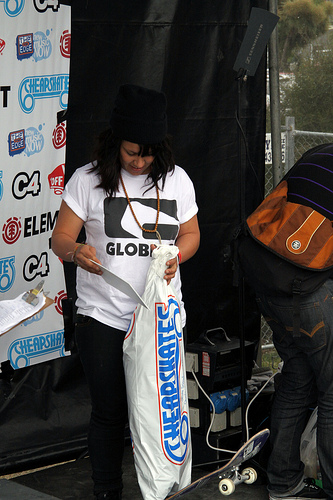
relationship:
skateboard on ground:
[163, 428, 271, 498] [114, 461, 253, 497]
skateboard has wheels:
[163, 428, 271, 498] [240, 466, 257, 484]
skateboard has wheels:
[163, 428, 271, 498] [217, 477, 236, 494]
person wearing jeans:
[255, 144, 331, 233] [255, 297, 331, 411]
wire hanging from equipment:
[189, 357, 283, 453] [64, 0, 279, 467]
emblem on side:
[6, 123, 32, 152] [2, 23, 63, 498]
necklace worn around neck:
[117, 170, 161, 233] [119, 165, 152, 175]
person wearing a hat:
[59, 104, 196, 362] [110, 93, 172, 143]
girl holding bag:
[49, 87, 200, 500] [112, 237, 190, 498]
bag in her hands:
[112, 237, 190, 498] [74, 233, 185, 281]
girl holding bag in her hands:
[49, 87, 200, 500] [74, 233, 185, 281]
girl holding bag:
[49, 87, 200, 500] [122, 243, 192, 500]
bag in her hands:
[122, 243, 192, 500] [75, 240, 193, 282]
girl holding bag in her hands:
[49, 87, 200, 500] [75, 240, 193, 282]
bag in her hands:
[122, 243, 192, 500] [61, 229, 182, 282]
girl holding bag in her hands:
[49, 87, 200, 500] [61, 229, 182, 282]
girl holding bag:
[51, 86, 290, 310] [122, 243, 192, 500]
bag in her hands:
[122, 243, 192, 500] [74, 243, 183, 281]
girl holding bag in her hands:
[51, 86, 290, 310] [74, 243, 183, 281]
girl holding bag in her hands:
[49, 87, 200, 500] [72, 241, 180, 288]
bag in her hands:
[122, 243, 192, 500] [72, 241, 180, 288]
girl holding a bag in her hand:
[49, 87, 200, 500] [164, 252, 179, 283]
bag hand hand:
[122, 243, 192, 500] [164, 252, 179, 283]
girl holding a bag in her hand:
[49, 87, 200, 500] [73, 243, 102, 275]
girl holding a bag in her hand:
[49, 87, 200, 500] [148, 244, 176, 283]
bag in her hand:
[122, 243, 192, 500] [73, 243, 102, 275]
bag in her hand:
[122, 243, 192, 500] [148, 244, 176, 283]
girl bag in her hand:
[49, 87, 200, 500] [163, 256, 178, 283]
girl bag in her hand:
[49, 87, 200, 500] [73, 243, 102, 275]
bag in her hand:
[122, 243, 192, 500] [163, 256, 178, 283]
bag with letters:
[122, 243, 192, 500] [151, 324, 179, 364]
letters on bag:
[151, 324, 179, 364] [122, 243, 192, 500]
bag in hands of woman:
[122, 243, 192, 500] [49, 81, 203, 499]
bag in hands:
[122, 243, 192, 500] [74, 239, 179, 283]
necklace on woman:
[117, 171, 160, 233] [54, 116, 202, 497]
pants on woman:
[68, 311, 127, 499] [56, 64, 245, 339]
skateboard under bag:
[163, 428, 271, 498] [122, 243, 192, 500]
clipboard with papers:
[1, 285, 55, 337] [0, 290, 39, 327]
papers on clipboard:
[0, 290, 39, 327] [1, 285, 55, 337]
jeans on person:
[237, 267, 332, 492] [244, 138, 327, 498]